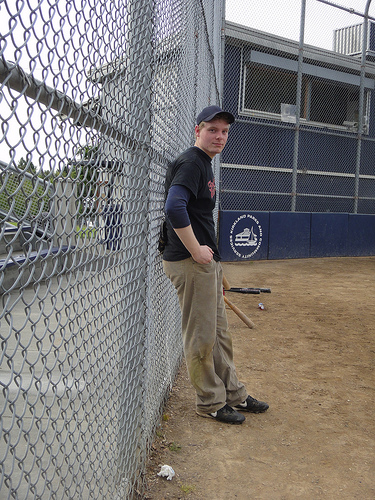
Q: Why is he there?
A: Posing.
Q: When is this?
A: Daytime.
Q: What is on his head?
A: Cap.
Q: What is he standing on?
A: Dirt.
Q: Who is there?
A: Young man.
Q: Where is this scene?
A: Baseball field.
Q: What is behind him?
A: Fence.